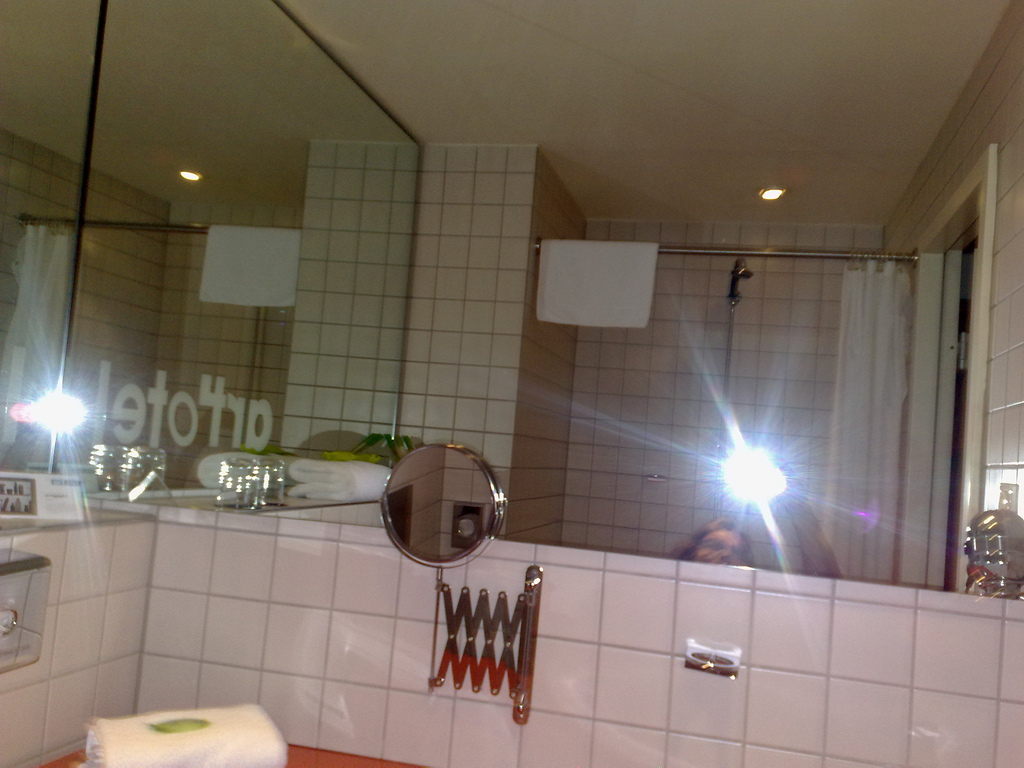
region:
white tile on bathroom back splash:
[266, 536, 340, 607]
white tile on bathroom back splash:
[323, 539, 400, 625]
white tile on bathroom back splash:
[194, 593, 271, 666]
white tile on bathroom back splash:
[250, 593, 330, 677]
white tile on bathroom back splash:
[317, 605, 395, 681]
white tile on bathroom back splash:
[377, 618, 458, 694]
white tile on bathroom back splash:
[374, 681, 451, 762]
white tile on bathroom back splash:
[251, 673, 324, 744]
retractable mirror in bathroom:
[351, 413, 575, 734]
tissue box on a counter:
[65, 690, 293, 763]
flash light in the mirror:
[691, 408, 815, 527]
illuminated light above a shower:
[733, 167, 804, 220]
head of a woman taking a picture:
[655, 499, 772, 580]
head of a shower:
[711, 242, 767, 321]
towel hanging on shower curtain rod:
[543, 217, 665, 360]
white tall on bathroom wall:
[180, 558, 387, 663]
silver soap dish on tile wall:
[665, 637, 760, 702]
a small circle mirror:
[370, 442, 520, 569]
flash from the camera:
[708, 442, 782, 510]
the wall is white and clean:
[114, 530, 943, 766]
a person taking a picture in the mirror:
[645, 407, 807, 578]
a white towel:
[541, 233, 659, 347]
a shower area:
[543, 224, 902, 551]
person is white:
[664, 509, 750, 571]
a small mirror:
[366, 439, 583, 695]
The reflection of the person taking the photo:
[661, 431, 843, 583]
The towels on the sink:
[69, 676, 292, 766]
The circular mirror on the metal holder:
[370, 436, 514, 574]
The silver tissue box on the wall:
[0, 548, 67, 679]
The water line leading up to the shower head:
[717, 308, 744, 521]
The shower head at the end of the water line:
[720, 245, 760, 306]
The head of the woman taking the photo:
[667, 513, 762, 577]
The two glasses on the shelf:
[204, 450, 290, 514]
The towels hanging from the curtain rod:
[196, 213, 668, 331]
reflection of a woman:
[642, 487, 836, 576]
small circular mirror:
[375, 433, 505, 571]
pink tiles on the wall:
[11, 525, 1023, 766]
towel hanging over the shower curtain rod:
[529, 235, 681, 330]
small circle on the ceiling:
[753, 180, 792, 209]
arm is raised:
[751, 466, 869, 590]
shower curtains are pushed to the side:
[800, 244, 928, 583]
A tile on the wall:
[596, 571, 676, 651]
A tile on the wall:
[828, 593, 914, 688]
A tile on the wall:
[740, 664, 824, 756]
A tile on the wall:
[588, 642, 674, 729]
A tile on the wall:
[319, 609, 397, 692]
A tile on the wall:
[261, 597, 337, 680]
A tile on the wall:
[190, 588, 276, 675]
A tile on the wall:
[43, 591, 113, 680]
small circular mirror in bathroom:
[375, 420, 532, 566]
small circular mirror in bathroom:
[374, 430, 521, 576]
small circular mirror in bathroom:
[373, 423, 520, 572]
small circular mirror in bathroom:
[367, 432, 529, 579]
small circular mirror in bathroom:
[364, 427, 524, 579]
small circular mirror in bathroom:
[362, 411, 534, 574]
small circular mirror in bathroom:
[352, 416, 524, 572]